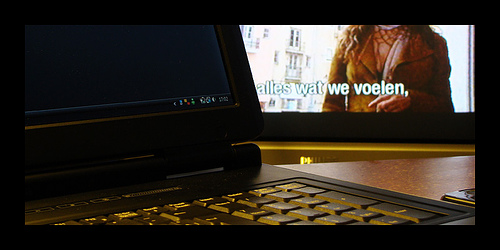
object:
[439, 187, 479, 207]
book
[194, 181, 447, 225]
keypad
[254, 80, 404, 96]
words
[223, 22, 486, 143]
tv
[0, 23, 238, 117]
screen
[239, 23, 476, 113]
screen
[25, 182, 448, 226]
keyboard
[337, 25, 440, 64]
brown hair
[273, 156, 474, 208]
countertop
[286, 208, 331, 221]
button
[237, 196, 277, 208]
button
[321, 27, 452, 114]
jacket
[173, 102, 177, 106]
icon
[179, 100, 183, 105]
icon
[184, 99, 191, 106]
icon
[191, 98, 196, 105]
icon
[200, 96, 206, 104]
icon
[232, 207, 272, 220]
button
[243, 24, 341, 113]
buildings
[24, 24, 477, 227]
laptop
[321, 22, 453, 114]
woman